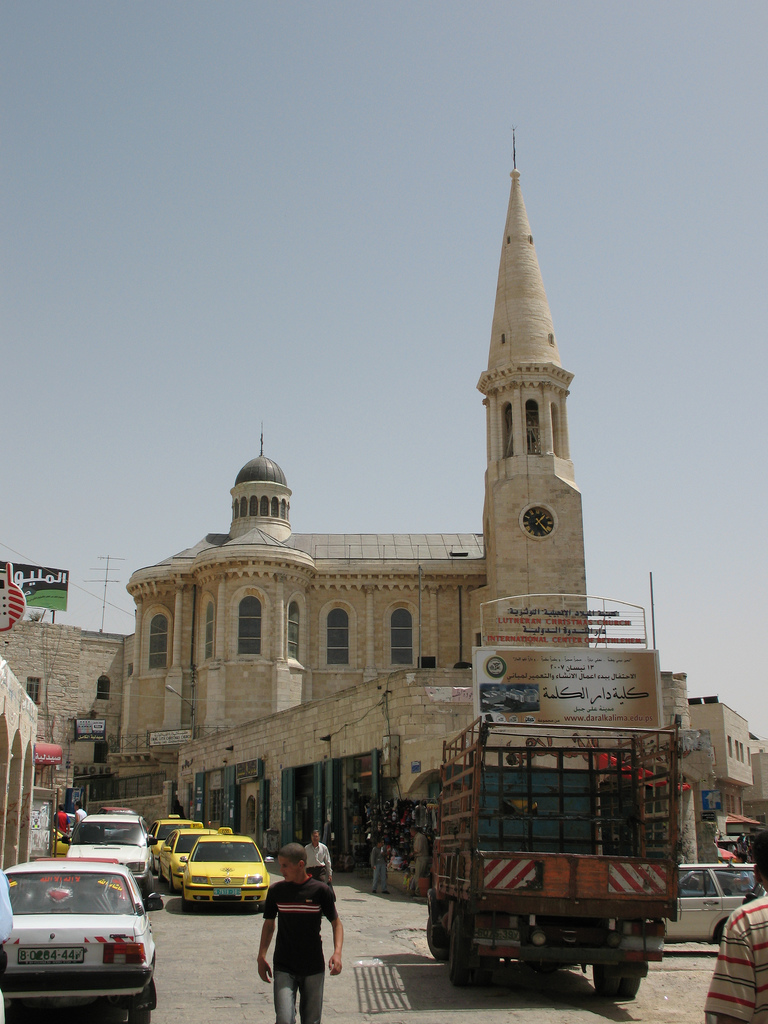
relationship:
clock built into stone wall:
[522, 505, 558, 544] [488, 470, 589, 645]